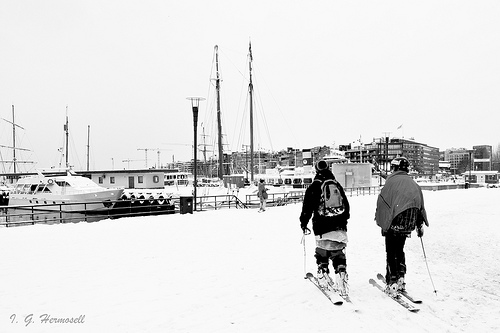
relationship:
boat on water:
[8, 176, 123, 212] [1, 208, 37, 222]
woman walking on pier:
[255, 178, 276, 223] [96, 148, 333, 226]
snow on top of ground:
[0, 188, 500, 333] [1, 185, 497, 331]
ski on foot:
[303, 270, 345, 306] [314, 265, 329, 289]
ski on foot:
[325, 273, 371, 317] [333, 286, 347, 297]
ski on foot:
[363, 278, 417, 313] [384, 281, 400, 299]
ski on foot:
[376, 267, 426, 304] [394, 277, 406, 291]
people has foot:
[374, 157, 424, 298] [314, 265, 329, 289]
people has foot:
[374, 157, 424, 298] [333, 286, 347, 297]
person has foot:
[300, 160, 351, 291] [384, 281, 400, 299]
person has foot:
[300, 160, 351, 291] [394, 277, 406, 291]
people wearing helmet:
[374, 157, 424, 298] [387, 155, 411, 172]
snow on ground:
[231, 274, 281, 306] [218, 272, 295, 294]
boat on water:
[0, 168, 126, 212] [2, 204, 157, 226]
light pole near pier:
[184, 94, 203, 210] [107, 183, 242, 212]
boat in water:
[0, 168, 126, 212] [2, 205, 115, 230]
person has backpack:
[300, 160, 351, 291] [319, 179, 344, 214]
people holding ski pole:
[374, 157, 424, 298] [417, 228, 443, 299]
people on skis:
[374, 157, 424, 298] [372, 270, 420, 313]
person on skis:
[302, 158, 353, 286] [306, 268, 357, 308]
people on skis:
[300, 157, 430, 302] [306, 265, 427, 313]